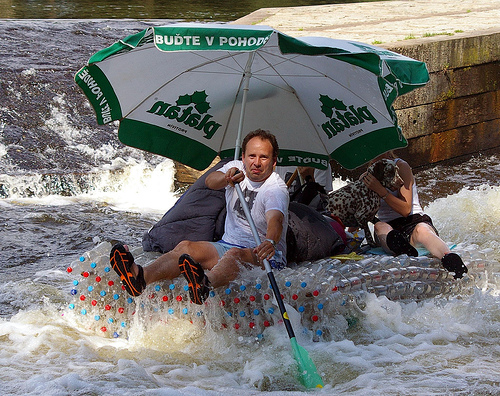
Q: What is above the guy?
A: An umbrella.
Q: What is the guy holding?
A: A oar.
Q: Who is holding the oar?
A: The guy.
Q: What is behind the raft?
A: Brown brick wall.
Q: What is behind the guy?
A: People and dogs.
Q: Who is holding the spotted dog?
A: The person in black and white.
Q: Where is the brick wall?
A: Behind the raft.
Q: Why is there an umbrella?
A: Shade.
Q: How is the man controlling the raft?
A: Oar.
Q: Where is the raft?
A: Water.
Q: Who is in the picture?
A: A man and a woman.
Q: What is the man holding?
A: A paddle.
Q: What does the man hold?
A: A paddle.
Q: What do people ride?
A: A raft.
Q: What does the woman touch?
A: A dog.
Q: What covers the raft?
A: A green and white umbrella.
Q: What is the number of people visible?
A: Four.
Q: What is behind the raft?
A: A stone wall.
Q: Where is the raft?
A: In splashing wavy water.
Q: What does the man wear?
A: White shirt and blue shorts.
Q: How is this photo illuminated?
A: Natural sun light.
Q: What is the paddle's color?
A: Green.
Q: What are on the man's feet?
A: Shoes.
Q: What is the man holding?
A: An oar.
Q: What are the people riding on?
A: A raft.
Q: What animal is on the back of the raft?
A: Dog.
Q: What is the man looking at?
A: The camera.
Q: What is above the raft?
A: Umbrella.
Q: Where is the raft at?
A: On the water.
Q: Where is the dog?
A: On the raft.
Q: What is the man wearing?
A: White shirt.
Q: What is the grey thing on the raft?
A: Sleeping bag.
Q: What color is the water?
A: White and gray.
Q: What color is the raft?
A: Clear, blue, and red.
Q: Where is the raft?
A: On the water.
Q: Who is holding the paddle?
A: The man.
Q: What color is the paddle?
A: Green, black, and silver.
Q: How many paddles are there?
A: One.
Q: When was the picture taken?
A: Daytime.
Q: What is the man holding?
A: A paddle.